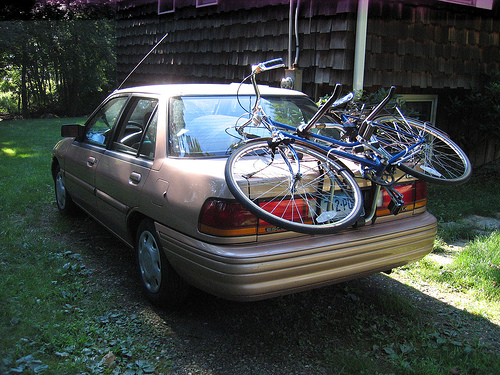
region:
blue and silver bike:
[172, 110, 442, 286]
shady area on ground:
[250, 260, 488, 355]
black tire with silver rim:
[116, 217, 166, 361]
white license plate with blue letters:
[290, 179, 370, 250]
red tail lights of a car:
[113, 165, 435, 292]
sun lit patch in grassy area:
[1, 122, 56, 162]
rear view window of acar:
[115, 98, 315, 183]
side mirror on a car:
[30, 118, 87, 155]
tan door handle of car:
[65, 153, 106, 178]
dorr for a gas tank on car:
[132, 166, 174, 227]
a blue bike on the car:
[224, 51, 476, 238]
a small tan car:
[49, 33, 443, 310]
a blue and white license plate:
[320, 193, 365, 220]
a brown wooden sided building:
[113, 1, 495, 178]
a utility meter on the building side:
[279, 0, 311, 91]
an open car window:
[113, 94, 157, 150]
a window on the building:
[396, 96, 442, 175]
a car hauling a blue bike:
[40, 28, 471, 313]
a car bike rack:
[297, 56, 401, 231]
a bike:
[219, 51, 474, 233]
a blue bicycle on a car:
[226, 82, 423, 224]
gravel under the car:
[129, 320, 201, 367]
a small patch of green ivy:
[89, 339, 139, 374]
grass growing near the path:
[19, 282, 53, 337]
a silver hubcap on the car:
[139, 238, 156, 280]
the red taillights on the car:
[203, 197, 285, 222]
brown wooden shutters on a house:
[209, 25, 245, 47]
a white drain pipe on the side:
[351, 4, 366, 88]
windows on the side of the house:
[153, 0, 227, 17]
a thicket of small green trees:
[12, 8, 101, 98]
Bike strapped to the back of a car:
[203, 53, 478, 252]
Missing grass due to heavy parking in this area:
[31, 195, 458, 355]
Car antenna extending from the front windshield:
[84, 22, 179, 97]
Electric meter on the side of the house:
[271, 2, 323, 95]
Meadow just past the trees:
[1, 59, 78, 124]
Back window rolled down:
[103, 95, 172, 175]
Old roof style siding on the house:
[126, 12, 271, 82]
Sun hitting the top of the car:
[105, 62, 312, 122]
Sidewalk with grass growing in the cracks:
[416, 185, 499, 280]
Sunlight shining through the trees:
[0, 132, 49, 176]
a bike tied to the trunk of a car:
[151, 33, 458, 250]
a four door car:
[1, 44, 340, 313]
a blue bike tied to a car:
[206, 70, 443, 223]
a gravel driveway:
[196, 278, 468, 371]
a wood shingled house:
[178, 20, 346, 82]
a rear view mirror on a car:
[38, 103, 100, 162]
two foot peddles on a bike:
[361, 162, 423, 234]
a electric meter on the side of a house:
[258, 44, 311, 114]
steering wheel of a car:
[86, 106, 148, 164]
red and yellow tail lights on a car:
[167, 158, 439, 265]